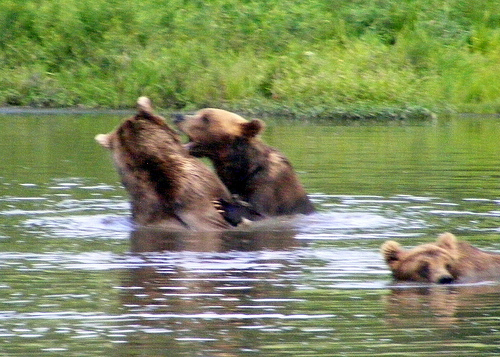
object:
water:
[0, 98, 500, 357]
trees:
[0, 0, 45, 68]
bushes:
[403, 17, 476, 95]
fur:
[115, 126, 199, 228]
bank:
[33, 76, 158, 116]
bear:
[381, 230, 498, 284]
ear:
[240, 118, 265, 136]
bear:
[171, 100, 317, 216]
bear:
[96, 96, 229, 228]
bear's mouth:
[174, 114, 197, 149]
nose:
[172, 112, 185, 123]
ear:
[136, 96, 155, 116]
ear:
[95, 133, 112, 148]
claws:
[214, 210, 224, 213]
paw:
[225, 199, 249, 223]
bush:
[39, 15, 70, 66]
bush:
[82, 35, 104, 71]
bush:
[117, 28, 143, 64]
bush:
[150, 31, 167, 59]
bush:
[174, 45, 198, 73]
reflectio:
[384, 278, 499, 341]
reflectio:
[230, 210, 320, 294]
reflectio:
[129, 208, 233, 289]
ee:
[200, 116, 209, 123]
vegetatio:
[2, 0, 498, 109]